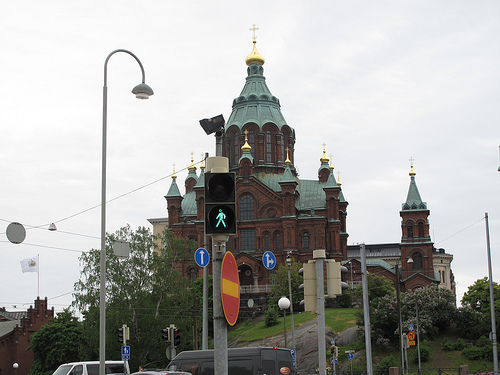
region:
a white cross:
[237, 17, 267, 60]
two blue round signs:
[188, 240, 282, 280]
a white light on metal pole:
[276, 292, 296, 348]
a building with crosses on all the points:
[138, 20, 465, 306]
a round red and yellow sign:
[220, 249, 245, 331]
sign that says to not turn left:
[406, 327, 417, 352]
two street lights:
[113, 320, 187, 360]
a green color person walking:
[208, 204, 233, 233]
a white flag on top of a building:
[19, 250, 52, 306]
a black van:
[159, 342, 295, 373]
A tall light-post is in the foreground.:
[95, 38, 160, 373]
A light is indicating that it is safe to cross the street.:
[197, 150, 240, 242]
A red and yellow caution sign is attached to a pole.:
[215, 247, 243, 330]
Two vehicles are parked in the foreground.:
[41, 338, 304, 373]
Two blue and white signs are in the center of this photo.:
[182, 242, 284, 274]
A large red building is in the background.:
[137, 15, 460, 324]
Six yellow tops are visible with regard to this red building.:
[165, 123, 421, 186]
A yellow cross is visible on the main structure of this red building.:
[241, 16, 268, 62]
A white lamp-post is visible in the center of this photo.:
[275, 291, 297, 352]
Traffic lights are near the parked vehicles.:
[105, 319, 192, 353]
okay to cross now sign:
[202, 172, 242, 234]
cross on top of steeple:
[241, 18, 267, 58]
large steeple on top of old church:
[213, 17, 299, 125]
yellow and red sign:
[215, 250, 251, 328]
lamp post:
[82, 41, 172, 163]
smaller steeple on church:
[377, 141, 444, 243]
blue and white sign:
[255, 246, 278, 280]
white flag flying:
[16, 246, 57, 301]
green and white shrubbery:
[372, 280, 478, 348]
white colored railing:
[241, 264, 312, 300]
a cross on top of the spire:
[242, 18, 264, 50]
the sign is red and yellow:
[215, 246, 245, 328]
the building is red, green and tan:
[142, 21, 461, 321]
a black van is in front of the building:
[161, 345, 302, 374]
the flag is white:
[16, 249, 43, 276]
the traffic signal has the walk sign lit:
[197, 144, 240, 374]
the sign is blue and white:
[190, 243, 209, 270]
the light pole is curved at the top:
[95, 45, 156, 372]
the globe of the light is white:
[277, 287, 291, 349]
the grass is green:
[202, 299, 367, 361]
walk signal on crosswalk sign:
[189, 161, 240, 246]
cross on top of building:
[228, 13, 286, 130]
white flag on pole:
[12, 245, 56, 299]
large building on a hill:
[144, 47, 459, 353]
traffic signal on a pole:
[291, 243, 356, 344]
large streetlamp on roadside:
[88, 38, 158, 370]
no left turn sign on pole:
[401, 313, 424, 360]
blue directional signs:
[190, 238, 288, 272]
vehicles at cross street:
[21, 328, 306, 373]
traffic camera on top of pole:
[183, 94, 250, 207]